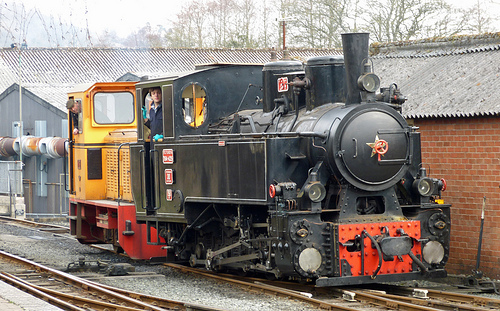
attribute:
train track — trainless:
[2, 248, 177, 309]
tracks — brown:
[0, 215, 497, 307]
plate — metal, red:
[337, 219, 425, 278]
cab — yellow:
[62, 80, 143, 207]